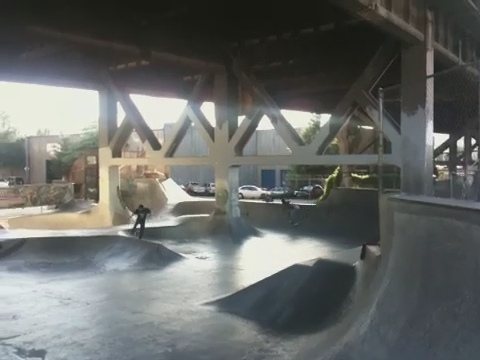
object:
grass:
[50, 185, 68, 204]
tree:
[58, 126, 99, 166]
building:
[142, 103, 362, 195]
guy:
[128, 204, 152, 240]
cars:
[268, 186, 290, 194]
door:
[261, 169, 275, 188]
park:
[0, 123, 478, 358]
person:
[280, 198, 295, 224]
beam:
[400, 41, 435, 195]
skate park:
[0, 191, 480, 360]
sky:
[0, 79, 477, 149]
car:
[238, 185, 271, 200]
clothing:
[131, 207, 151, 239]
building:
[23, 133, 48, 182]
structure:
[0, 0, 480, 226]